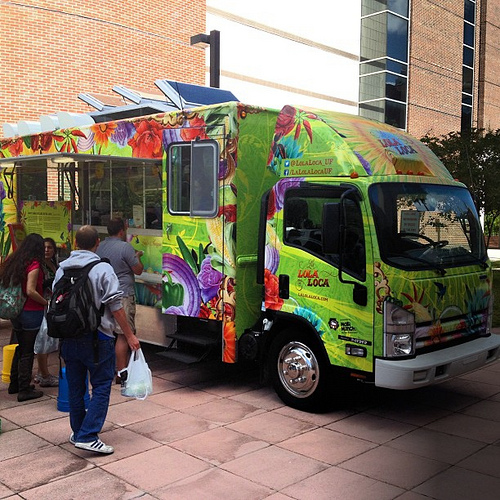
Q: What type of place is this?
A: It is a road.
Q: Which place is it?
A: It is a road.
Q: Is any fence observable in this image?
A: No, there are no fences.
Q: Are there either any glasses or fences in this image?
A: No, there are no fences or glasses.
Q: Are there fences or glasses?
A: No, there are no fences or glasses.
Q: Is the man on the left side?
A: Yes, the man is on the left of the image.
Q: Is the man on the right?
A: No, the man is on the left of the image.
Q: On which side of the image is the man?
A: The man is on the left of the image.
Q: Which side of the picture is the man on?
A: The man is on the left of the image.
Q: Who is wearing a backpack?
A: The man is wearing a backpack.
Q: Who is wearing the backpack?
A: The man is wearing a backpack.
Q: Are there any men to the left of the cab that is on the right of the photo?
A: Yes, there is a man to the left of the taxi.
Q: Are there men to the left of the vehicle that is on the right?
A: Yes, there is a man to the left of the taxi.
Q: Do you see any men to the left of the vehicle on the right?
A: Yes, there is a man to the left of the taxi.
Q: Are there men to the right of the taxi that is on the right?
A: No, the man is to the left of the taxi cab.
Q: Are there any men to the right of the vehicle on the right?
A: No, the man is to the left of the taxi cab.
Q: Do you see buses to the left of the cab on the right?
A: No, there is a man to the left of the taxi cab.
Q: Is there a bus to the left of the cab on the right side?
A: No, there is a man to the left of the taxi cab.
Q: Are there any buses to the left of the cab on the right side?
A: No, there is a man to the left of the taxi cab.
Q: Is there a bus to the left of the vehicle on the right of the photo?
A: No, there is a man to the left of the taxi cab.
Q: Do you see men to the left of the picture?
A: Yes, there is a man to the left of the picture.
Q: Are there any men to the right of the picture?
A: No, the man is to the left of the picture.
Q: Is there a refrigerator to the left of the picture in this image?
A: No, there is a man to the left of the picture.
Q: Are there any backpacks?
A: Yes, there is a backpack.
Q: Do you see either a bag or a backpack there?
A: Yes, there is a backpack.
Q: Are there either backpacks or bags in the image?
A: Yes, there is a backpack.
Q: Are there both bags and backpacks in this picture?
A: Yes, there are both a backpack and a bag.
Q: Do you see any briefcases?
A: No, there are no briefcases.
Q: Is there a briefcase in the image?
A: No, there are no briefcases.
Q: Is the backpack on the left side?
A: Yes, the backpack is on the left of the image.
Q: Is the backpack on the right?
A: No, the backpack is on the left of the image.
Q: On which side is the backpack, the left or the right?
A: The backpack is on the left of the image.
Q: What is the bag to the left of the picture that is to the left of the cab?
A: The bag is a backpack.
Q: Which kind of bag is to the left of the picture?
A: The bag is a backpack.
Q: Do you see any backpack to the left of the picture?
A: Yes, there is a backpack to the left of the picture.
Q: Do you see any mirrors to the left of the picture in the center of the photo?
A: No, there is a backpack to the left of the picture.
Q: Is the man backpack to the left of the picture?
A: Yes, the backpack is to the left of the picture.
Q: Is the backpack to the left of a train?
A: No, the backpack is to the left of the picture.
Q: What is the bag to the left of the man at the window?
A: The bag is a backpack.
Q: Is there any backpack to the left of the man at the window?
A: Yes, there is a backpack to the left of the man.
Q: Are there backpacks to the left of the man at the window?
A: Yes, there is a backpack to the left of the man.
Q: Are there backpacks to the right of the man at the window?
A: No, the backpack is to the left of the man.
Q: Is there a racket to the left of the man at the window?
A: No, there is a backpack to the left of the man.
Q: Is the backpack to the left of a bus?
A: No, the backpack is to the left of the man.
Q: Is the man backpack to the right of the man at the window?
A: No, the backpack is to the left of the man.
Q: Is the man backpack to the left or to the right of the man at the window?
A: The backpack is to the left of the man.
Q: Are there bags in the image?
A: Yes, there is a bag.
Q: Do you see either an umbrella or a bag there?
A: Yes, there is a bag.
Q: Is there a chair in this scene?
A: No, there are no chairs.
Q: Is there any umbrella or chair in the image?
A: No, there are no chairs or umbrellas.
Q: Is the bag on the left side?
A: Yes, the bag is on the left of the image.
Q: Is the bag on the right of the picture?
A: No, the bag is on the left of the image.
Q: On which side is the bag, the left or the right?
A: The bag is on the left of the image.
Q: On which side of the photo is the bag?
A: The bag is on the left of the image.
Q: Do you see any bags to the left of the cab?
A: Yes, there is a bag to the left of the cab.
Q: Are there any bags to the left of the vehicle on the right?
A: Yes, there is a bag to the left of the cab.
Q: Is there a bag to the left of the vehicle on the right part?
A: Yes, there is a bag to the left of the cab.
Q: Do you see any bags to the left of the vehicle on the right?
A: Yes, there is a bag to the left of the cab.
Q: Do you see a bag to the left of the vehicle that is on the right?
A: Yes, there is a bag to the left of the cab.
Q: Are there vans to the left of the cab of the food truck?
A: No, there is a bag to the left of the taxi.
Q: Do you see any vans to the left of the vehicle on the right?
A: No, there is a bag to the left of the taxi.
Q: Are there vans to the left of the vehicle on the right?
A: No, there is a bag to the left of the taxi.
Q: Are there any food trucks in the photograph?
A: Yes, there is a food truck.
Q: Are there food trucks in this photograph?
A: Yes, there is a food truck.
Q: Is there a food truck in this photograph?
A: Yes, there is a food truck.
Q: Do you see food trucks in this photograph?
A: Yes, there is a food truck.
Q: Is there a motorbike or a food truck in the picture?
A: Yes, there is a food truck.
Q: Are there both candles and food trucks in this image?
A: No, there is a food truck but no candles.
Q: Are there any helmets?
A: No, there are no helmets.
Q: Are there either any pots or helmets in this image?
A: No, there are no helmets or pots.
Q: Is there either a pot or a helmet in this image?
A: No, there are no helmets or pots.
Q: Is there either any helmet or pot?
A: No, there are no helmets or pots.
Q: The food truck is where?
A: The food truck is on the road.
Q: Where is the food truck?
A: The food truck is on the road.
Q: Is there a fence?
A: No, there are no fences.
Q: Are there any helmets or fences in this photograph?
A: No, there are no fences or helmets.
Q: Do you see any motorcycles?
A: No, there are no motorcycles.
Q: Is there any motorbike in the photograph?
A: No, there are no motorcycles.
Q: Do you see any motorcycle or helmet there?
A: No, there are no motorcycles or helmets.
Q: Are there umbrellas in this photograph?
A: No, there are no umbrellas.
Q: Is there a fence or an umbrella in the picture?
A: No, there are no umbrellas or fences.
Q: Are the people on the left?
A: Yes, the people are on the left of the image.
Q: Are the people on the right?
A: No, the people are on the left of the image.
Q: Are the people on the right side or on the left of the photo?
A: The people are on the left of the image.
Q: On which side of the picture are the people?
A: The people are on the left of the image.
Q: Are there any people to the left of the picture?
A: Yes, there are people to the left of the picture.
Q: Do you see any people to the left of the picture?
A: Yes, there are people to the left of the picture.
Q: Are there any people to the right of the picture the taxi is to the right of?
A: No, the people are to the left of the picture.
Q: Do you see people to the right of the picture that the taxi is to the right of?
A: No, the people are to the left of the picture.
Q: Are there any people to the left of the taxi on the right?
A: Yes, there are people to the left of the cab.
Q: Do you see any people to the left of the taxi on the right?
A: Yes, there are people to the left of the cab.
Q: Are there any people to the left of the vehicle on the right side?
A: Yes, there are people to the left of the cab.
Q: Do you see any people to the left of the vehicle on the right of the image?
A: Yes, there are people to the left of the cab.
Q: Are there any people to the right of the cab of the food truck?
A: No, the people are to the left of the cab.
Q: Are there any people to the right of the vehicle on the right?
A: No, the people are to the left of the cab.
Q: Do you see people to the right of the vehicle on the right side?
A: No, the people are to the left of the cab.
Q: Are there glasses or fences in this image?
A: No, there are no fences or glasses.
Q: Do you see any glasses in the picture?
A: No, there are no glasses.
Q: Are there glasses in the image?
A: No, there are no glasses.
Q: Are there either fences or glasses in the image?
A: No, there are no glasses or fences.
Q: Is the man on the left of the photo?
A: Yes, the man is on the left of the image.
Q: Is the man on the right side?
A: No, the man is on the left of the image.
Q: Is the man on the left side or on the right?
A: The man is on the left of the image.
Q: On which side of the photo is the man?
A: The man is on the left of the image.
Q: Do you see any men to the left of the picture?
A: Yes, there is a man to the left of the picture.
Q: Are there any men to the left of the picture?
A: Yes, there is a man to the left of the picture.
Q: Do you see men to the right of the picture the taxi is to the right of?
A: No, the man is to the left of the picture.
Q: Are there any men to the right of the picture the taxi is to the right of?
A: No, the man is to the left of the picture.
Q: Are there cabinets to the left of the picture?
A: No, there is a man to the left of the picture.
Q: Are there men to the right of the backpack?
A: Yes, there is a man to the right of the backpack.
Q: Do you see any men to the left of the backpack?
A: No, the man is to the right of the backpack.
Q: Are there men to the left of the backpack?
A: No, the man is to the right of the backpack.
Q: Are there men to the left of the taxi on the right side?
A: Yes, there is a man to the left of the taxi cab.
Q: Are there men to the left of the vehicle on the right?
A: Yes, there is a man to the left of the taxi cab.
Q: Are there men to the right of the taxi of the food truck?
A: No, the man is to the left of the taxi.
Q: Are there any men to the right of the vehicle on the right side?
A: No, the man is to the left of the taxi.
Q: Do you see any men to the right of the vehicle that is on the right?
A: No, the man is to the left of the taxi.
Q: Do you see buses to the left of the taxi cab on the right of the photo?
A: No, there is a man to the left of the taxi cab.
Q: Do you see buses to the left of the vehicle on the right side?
A: No, there is a man to the left of the taxi cab.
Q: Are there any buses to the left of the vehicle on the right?
A: No, there is a man to the left of the taxi cab.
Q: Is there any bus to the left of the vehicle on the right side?
A: No, there is a man to the left of the taxi cab.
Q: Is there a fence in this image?
A: No, there are no fences.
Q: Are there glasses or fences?
A: No, there are no fences or glasses.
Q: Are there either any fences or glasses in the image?
A: No, there are no fences or glasses.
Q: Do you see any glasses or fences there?
A: No, there are no fences or glasses.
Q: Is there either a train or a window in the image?
A: Yes, there is a window.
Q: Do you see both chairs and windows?
A: No, there is a window but no chairs.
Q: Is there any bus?
A: No, there are no buses.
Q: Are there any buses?
A: No, there are no buses.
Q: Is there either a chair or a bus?
A: No, there are no buses or chairs.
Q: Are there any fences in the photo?
A: No, there are no fences.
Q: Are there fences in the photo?
A: No, there are no fences.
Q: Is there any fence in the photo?
A: No, there are no fences.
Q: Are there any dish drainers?
A: No, there are no dish drainers.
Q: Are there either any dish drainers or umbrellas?
A: No, there are no dish drainers or umbrellas.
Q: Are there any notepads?
A: No, there are no notepads.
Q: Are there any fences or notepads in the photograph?
A: No, there are no notepads or fences.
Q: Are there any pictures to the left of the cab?
A: Yes, there is a picture to the left of the cab.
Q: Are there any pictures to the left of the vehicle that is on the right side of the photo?
A: Yes, there is a picture to the left of the cab.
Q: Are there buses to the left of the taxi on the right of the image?
A: No, there is a picture to the left of the cab.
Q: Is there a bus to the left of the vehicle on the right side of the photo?
A: No, there is a picture to the left of the cab.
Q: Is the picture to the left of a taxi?
A: Yes, the picture is to the left of a taxi.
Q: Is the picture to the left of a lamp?
A: No, the picture is to the left of a taxi.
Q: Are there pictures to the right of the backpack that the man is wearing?
A: Yes, there is a picture to the right of the backpack.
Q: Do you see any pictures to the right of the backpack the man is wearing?
A: Yes, there is a picture to the right of the backpack.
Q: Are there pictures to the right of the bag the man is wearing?
A: Yes, there is a picture to the right of the backpack.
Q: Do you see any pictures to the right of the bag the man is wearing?
A: Yes, there is a picture to the right of the backpack.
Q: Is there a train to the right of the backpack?
A: No, there is a picture to the right of the backpack.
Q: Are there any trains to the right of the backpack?
A: No, there is a picture to the right of the backpack.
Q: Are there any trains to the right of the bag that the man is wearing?
A: No, there is a picture to the right of the backpack.